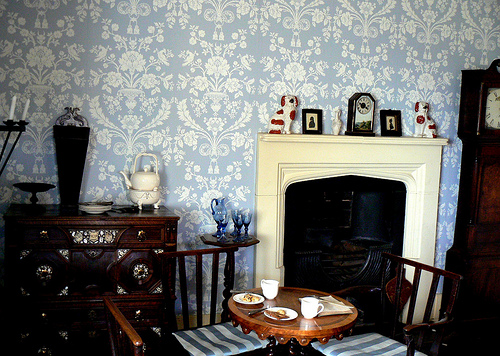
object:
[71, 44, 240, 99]
blue wallpaper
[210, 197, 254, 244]
glassware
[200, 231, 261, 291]
table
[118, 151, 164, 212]
kettle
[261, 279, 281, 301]
cups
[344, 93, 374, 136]
clock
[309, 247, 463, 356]
chair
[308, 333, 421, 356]
stripes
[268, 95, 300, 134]
dog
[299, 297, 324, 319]
cup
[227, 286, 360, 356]
bars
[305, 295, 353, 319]
paper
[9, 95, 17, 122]
candle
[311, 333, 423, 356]
seat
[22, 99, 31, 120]
candles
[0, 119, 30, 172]
holders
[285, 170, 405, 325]
fireplace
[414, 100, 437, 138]
figurine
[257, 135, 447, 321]
mantel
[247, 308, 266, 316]
cutlery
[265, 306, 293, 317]
snack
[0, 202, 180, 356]
shelf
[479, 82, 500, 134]
clock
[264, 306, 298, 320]
saucer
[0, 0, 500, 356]
kitchen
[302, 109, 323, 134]
photo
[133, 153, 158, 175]
handle